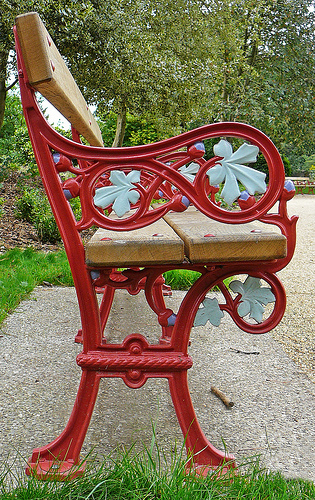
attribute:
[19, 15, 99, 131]
back — wooden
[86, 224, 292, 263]
seat — wooden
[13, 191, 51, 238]
bush — small, green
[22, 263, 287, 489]
legs — red 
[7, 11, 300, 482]
bench — park, red, metal, ornate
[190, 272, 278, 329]
leaf design — white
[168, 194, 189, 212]
flower — red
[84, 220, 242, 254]
bolts — red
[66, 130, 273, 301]
seat — wooden, bench, park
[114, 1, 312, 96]
trees — green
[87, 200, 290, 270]
seat — wood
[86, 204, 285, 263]
seat — wooden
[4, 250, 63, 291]
grass — patch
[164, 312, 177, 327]
tip — white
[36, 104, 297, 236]
arms — ornamental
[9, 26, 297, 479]
metal work — ornamental